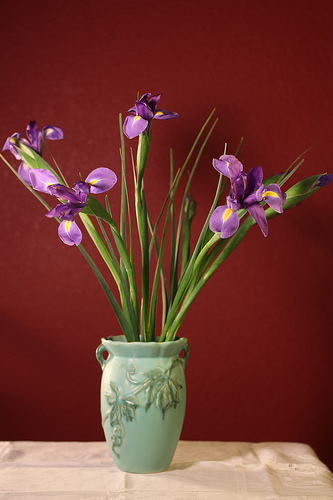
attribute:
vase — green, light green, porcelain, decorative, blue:
[93, 333, 196, 474]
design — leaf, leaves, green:
[102, 362, 179, 461]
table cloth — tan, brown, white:
[1, 442, 331, 499]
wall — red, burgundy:
[0, 2, 331, 474]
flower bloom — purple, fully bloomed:
[44, 166, 123, 251]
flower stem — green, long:
[127, 125, 158, 341]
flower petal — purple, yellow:
[123, 115, 149, 140]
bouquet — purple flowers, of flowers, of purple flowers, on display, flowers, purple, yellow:
[6, 89, 321, 345]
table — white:
[1, 440, 331, 500]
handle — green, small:
[94, 343, 110, 367]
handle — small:
[175, 338, 189, 360]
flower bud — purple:
[232, 176, 263, 210]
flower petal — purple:
[154, 110, 175, 121]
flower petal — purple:
[85, 166, 119, 194]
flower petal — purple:
[212, 151, 242, 177]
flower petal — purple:
[208, 204, 236, 237]